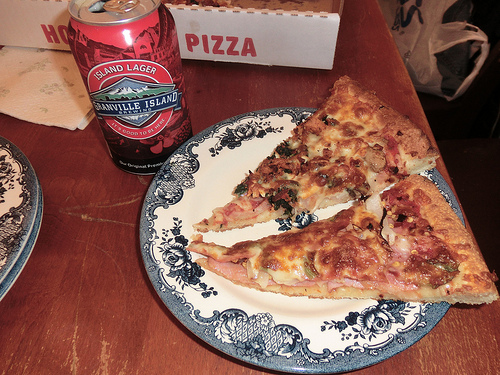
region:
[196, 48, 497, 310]
two slices of pizza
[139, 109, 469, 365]
white plate with blue design edges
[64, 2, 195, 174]
a red can of "island lager" beer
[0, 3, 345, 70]
a cardboard box of pizza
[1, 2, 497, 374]
a scrtached wooden table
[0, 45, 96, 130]
naplkins under sid eof pizza box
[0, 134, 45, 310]
stack of unused plates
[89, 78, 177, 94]
a mountain on can of beer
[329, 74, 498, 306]
crust on pizza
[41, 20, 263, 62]
red letters on white pizza box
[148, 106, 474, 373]
pizza is on the plate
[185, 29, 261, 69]
PIZZA written on the pizza box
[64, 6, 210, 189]
can of lager on the table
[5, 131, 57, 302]
stack of two dishes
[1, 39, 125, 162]
napkins under the pizza box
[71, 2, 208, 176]
can is red with a label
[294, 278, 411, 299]
ham on the slice of pizza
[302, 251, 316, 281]
green pepper on the pizza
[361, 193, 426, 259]
onion on the pizza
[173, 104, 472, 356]
two slices of pizza on a plate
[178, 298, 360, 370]
blue patter on a white plate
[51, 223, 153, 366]
distressed wood surface of the table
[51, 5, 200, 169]
a red can of beer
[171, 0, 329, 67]
a white pizza box on the table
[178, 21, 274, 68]
red lettering on the pizza box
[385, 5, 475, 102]
white plastic bag on the floor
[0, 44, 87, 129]
white napkin on the table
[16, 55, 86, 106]
green floral pattern on the napkin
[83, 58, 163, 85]
white lettering on the red beer can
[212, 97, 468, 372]
two slices of pizza on plate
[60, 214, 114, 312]
table made of wood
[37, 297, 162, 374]
table made of wood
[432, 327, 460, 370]
table made of wood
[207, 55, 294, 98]
table made of wood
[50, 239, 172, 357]
table made of wood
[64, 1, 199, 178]
A CAN OF BEER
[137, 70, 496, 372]
TWO SLICES OF PIZZA ON A PLATE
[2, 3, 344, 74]
A WHITE PIZZA BOX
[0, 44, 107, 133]
A WHITE NAPKIN ON THE TABLE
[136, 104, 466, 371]
A BLUE AND WHITE PLATE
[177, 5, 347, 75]
THE WORD PIZZA ON THE SIDE OF A BOX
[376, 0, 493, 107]
A WHITE PLASTIC BAG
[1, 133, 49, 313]
TWO STACKED PLATED ON THE TABLE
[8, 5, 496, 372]
A BROWN WOODEN TABLE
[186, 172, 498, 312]
A SLICE OF PIZZA